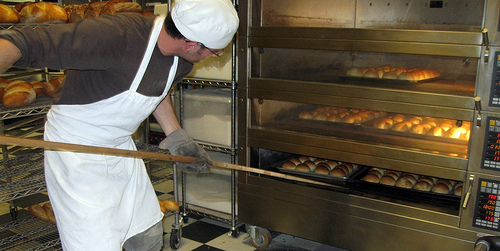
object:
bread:
[326, 169, 344, 178]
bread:
[364, 174, 382, 184]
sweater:
[0, 12, 195, 105]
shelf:
[261, 68, 477, 110]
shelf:
[257, 26, 484, 46]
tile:
[179, 218, 229, 242]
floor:
[161, 210, 274, 250]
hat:
[169, 0, 239, 51]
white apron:
[42, 15, 179, 251]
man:
[0, 0, 240, 251]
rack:
[0, 140, 173, 203]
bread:
[1, 2, 19, 21]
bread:
[21, 2, 68, 23]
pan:
[336, 76, 446, 85]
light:
[435, 118, 472, 144]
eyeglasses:
[185, 40, 227, 58]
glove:
[157, 126, 214, 178]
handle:
[0, 134, 199, 163]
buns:
[380, 177, 396, 187]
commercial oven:
[236, 0, 500, 251]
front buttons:
[480, 182, 487, 187]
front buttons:
[494, 165, 499, 168]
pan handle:
[0, 135, 349, 191]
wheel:
[248, 225, 267, 250]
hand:
[165, 141, 215, 175]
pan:
[344, 166, 465, 208]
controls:
[471, 178, 499, 230]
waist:
[46, 89, 141, 137]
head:
[164, 0, 238, 63]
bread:
[0, 79, 36, 107]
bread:
[392, 177, 414, 190]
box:
[171, 87, 236, 148]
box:
[172, 146, 241, 218]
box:
[186, 42, 240, 84]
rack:
[182, 76, 233, 86]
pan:
[278, 166, 366, 189]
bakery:
[0, 0, 499, 251]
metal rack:
[279, 119, 467, 153]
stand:
[236, 0, 500, 250]